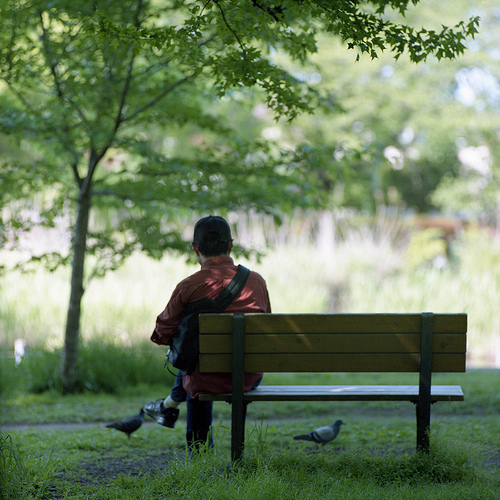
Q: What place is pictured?
A: It is a park.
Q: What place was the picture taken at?
A: It was taken at the park.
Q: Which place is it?
A: It is a park.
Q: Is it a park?
A: Yes, it is a park.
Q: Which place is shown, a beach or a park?
A: It is a park.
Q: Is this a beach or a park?
A: It is a park.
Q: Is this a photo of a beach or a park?
A: It is showing a park.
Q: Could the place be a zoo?
A: No, it is a park.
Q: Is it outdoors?
A: Yes, it is outdoors.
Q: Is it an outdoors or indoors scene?
A: It is outdoors.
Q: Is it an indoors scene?
A: No, it is outdoors.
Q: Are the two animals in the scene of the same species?
A: Yes, all the animals are birds.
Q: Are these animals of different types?
A: No, all the animals are birds.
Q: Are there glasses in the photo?
A: No, there are no glasses.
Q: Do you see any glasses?
A: No, there are no glasses.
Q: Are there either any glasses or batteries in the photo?
A: No, there are no glasses or batteries.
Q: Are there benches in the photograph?
A: Yes, there is a bench.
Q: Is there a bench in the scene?
A: Yes, there is a bench.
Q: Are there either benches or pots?
A: Yes, there is a bench.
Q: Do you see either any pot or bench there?
A: Yes, there is a bench.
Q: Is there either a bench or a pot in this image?
A: Yes, there is a bench.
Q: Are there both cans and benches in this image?
A: No, there is a bench but no cans.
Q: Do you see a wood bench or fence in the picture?
A: Yes, there is a wood bench.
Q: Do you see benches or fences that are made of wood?
A: Yes, the bench is made of wood.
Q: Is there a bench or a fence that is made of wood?
A: Yes, the bench is made of wood.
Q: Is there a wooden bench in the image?
A: Yes, there is a wood bench.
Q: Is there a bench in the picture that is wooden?
A: Yes, there is a bench that is wooden.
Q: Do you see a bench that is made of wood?
A: Yes, there is a bench that is made of wood.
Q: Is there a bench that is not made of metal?
A: Yes, there is a bench that is made of wood.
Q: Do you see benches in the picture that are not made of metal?
A: Yes, there is a bench that is made of wood.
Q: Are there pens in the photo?
A: No, there are no pens.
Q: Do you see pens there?
A: No, there are no pens.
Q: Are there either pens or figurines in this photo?
A: No, there are no pens or figurines.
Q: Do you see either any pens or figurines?
A: No, there are no pens or figurines.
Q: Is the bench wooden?
A: Yes, the bench is wooden.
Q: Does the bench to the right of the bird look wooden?
A: Yes, the bench is wooden.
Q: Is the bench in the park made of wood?
A: Yes, the bench is made of wood.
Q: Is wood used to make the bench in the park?
A: Yes, the bench is made of wood.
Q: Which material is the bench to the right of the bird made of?
A: The bench is made of wood.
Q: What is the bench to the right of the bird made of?
A: The bench is made of wood.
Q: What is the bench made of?
A: The bench is made of wood.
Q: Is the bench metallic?
A: No, the bench is wooden.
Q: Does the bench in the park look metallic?
A: No, the bench is wooden.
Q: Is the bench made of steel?
A: No, the bench is made of wood.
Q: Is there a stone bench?
A: No, there is a bench but it is made of wood.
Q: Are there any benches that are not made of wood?
A: No, there is a bench but it is made of wood.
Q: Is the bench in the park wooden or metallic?
A: The bench is wooden.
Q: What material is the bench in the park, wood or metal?
A: The bench is made of wood.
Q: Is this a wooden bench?
A: Yes, this is a wooden bench.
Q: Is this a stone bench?
A: No, this is a wooden bench.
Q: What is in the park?
A: The bench is in the park.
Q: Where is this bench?
A: The bench is in the park.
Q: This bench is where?
A: The bench is in the park.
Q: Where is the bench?
A: The bench is in the park.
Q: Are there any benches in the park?
A: Yes, there is a bench in the park.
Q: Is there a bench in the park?
A: Yes, there is a bench in the park.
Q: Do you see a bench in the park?
A: Yes, there is a bench in the park.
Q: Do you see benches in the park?
A: Yes, there is a bench in the park.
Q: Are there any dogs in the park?
A: No, there is a bench in the park.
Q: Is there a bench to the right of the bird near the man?
A: Yes, there is a bench to the right of the bird.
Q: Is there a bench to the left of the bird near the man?
A: No, the bench is to the right of the bird.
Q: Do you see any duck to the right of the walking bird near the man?
A: No, there is a bench to the right of the bird.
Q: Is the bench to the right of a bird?
A: Yes, the bench is to the right of a bird.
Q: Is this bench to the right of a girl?
A: No, the bench is to the right of a bird.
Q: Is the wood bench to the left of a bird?
A: No, the bench is to the right of a bird.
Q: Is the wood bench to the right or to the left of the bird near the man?
A: The bench is to the right of the bird.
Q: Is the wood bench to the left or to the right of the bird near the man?
A: The bench is to the right of the bird.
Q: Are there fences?
A: No, there are no fences.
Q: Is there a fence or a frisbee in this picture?
A: No, there are no fences or frisbees.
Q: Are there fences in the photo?
A: No, there are no fences.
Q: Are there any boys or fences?
A: No, there are no fences or boys.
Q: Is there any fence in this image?
A: No, there are no fences.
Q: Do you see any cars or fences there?
A: No, there are no fences or cars.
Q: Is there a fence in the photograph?
A: No, there are no fences.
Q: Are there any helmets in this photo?
A: No, there are no helmets.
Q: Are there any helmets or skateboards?
A: No, there are no helmets or skateboards.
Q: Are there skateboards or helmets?
A: No, there are no helmets or skateboards.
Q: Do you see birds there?
A: Yes, there is a bird.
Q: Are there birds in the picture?
A: Yes, there is a bird.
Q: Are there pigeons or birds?
A: Yes, there is a bird.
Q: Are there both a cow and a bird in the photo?
A: No, there is a bird but no cows.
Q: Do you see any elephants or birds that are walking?
A: Yes, the bird is walking.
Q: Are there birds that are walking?
A: Yes, there is a bird that is walking.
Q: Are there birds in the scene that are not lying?
A: Yes, there is a bird that is walking.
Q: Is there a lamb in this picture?
A: No, there are no lambs.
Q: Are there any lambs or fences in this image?
A: No, there are no lambs or fences.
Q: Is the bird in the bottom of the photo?
A: Yes, the bird is in the bottom of the image.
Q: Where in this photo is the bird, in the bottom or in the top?
A: The bird is in the bottom of the image.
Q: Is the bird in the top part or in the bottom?
A: The bird is in the bottom of the image.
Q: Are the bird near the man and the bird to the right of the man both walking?
A: Yes, both the bird and the bird are walking.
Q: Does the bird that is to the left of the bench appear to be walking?
A: Yes, the bird is walking.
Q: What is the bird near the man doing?
A: The bird is walking.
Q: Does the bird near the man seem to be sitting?
A: No, the bird is walking.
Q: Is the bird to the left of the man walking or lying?
A: The bird is walking.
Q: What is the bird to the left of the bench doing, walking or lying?
A: The bird is walking.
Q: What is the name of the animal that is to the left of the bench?
A: The animal is a bird.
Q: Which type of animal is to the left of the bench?
A: The animal is a bird.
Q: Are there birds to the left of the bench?
A: Yes, there is a bird to the left of the bench.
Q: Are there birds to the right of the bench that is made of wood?
A: No, the bird is to the left of the bench.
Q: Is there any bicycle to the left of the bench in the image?
A: No, there is a bird to the left of the bench.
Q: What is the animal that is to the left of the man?
A: The animal is a bird.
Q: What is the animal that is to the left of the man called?
A: The animal is a bird.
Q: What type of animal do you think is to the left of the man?
A: The animal is a bird.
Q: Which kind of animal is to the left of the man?
A: The animal is a bird.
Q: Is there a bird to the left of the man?
A: Yes, there is a bird to the left of the man.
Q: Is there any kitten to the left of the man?
A: No, there is a bird to the left of the man.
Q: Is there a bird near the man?
A: Yes, there is a bird near the man.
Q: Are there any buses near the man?
A: No, there is a bird near the man.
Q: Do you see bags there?
A: Yes, there is a bag.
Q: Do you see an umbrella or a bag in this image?
A: Yes, there is a bag.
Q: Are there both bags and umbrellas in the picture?
A: No, there is a bag but no umbrellas.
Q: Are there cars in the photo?
A: No, there are no cars.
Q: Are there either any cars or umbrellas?
A: No, there are no cars or umbrellas.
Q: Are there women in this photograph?
A: No, there are no women.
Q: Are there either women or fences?
A: No, there are no women or fences.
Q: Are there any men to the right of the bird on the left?
A: Yes, there is a man to the right of the bird.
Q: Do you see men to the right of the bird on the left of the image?
A: Yes, there is a man to the right of the bird.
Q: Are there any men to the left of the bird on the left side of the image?
A: No, the man is to the right of the bird.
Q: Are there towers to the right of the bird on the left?
A: No, there is a man to the right of the bird.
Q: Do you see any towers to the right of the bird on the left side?
A: No, there is a man to the right of the bird.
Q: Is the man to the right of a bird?
A: Yes, the man is to the right of a bird.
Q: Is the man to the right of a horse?
A: No, the man is to the right of a bird.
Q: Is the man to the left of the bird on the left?
A: No, the man is to the right of the bird.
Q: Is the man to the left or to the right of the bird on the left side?
A: The man is to the right of the bird.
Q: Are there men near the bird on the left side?
A: Yes, there is a man near the bird.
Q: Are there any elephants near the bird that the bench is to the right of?
A: No, there is a man near the bird.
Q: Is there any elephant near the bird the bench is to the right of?
A: No, there is a man near the bird.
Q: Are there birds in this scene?
A: Yes, there is a bird.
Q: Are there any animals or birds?
A: Yes, there is a bird.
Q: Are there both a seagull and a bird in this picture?
A: No, there is a bird but no seagulls.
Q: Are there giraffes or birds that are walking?
A: Yes, the bird is walking.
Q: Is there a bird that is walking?
A: Yes, there is a bird that is walking.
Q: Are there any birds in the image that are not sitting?
A: Yes, there is a bird that is walking.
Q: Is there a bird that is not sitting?
A: Yes, there is a bird that is walking.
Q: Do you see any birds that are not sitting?
A: Yes, there is a bird that is walking .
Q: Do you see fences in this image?
A: No, there are no fences.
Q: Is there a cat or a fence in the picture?
A: No, there are no fences or cats.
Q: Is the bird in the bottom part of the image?
A: Yes, the bird is in the bottom of the image.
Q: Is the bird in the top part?
A: No, the bird is in the bottom of the image.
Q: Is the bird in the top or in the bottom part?
A: The bird is in the bottom of the image.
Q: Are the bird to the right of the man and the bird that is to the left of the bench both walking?
A: Yes, both the bird and the bird are walking.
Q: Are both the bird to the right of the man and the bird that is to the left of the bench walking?
A: Yes, both the bird and the bird are walking.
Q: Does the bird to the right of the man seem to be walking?
A: Yes, the bird is walking.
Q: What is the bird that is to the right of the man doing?
A: The bird is walking.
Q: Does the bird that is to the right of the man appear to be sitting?
A: No, the bird is walking.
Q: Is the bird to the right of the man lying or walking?
A: The bird is walking.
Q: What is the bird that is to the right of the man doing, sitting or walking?
A: The bird is walking.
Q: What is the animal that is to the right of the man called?
A: The animal is a bird.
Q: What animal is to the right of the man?
A: The animal is a bird.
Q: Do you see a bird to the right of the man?
A: Yes, there is a bird to the right of the man.